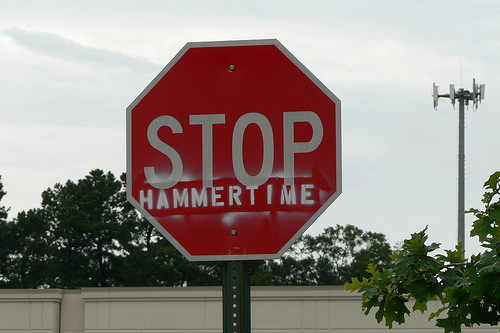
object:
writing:
[136, 179, 317, 210]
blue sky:
[332, 2, 482, 48]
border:
[186, 38, 276, 49]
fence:
[0, 287, 222, 330]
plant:
[347, 168, 500, 333]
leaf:
[344, 273, 368, 293]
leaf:
[412, 296, 431, 315]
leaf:
[437, 241, 467, 264]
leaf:
[424, 305, 447, 320]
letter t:
[190, 112, 227, 189]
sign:
[124, 37, 344, 267]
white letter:
[138, 190, 154, 210]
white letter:
[156, 185, 167, 208]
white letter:
[172, 186, 189, 208]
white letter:
[190, 189, 210, 207]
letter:
[191, 187, 209, 208]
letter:
[226, 185, 244, 206]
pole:
[218, 258, 251, 331]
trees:
[0, 168, 400, 286]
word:
[141, 111, 321, 193]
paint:
[134, 181, 320, 210]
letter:
[142, 114, 184, 190]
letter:
[231, 111, 275, 189]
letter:
[280, 109, 325, 186]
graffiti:
[138, 183, 317, 210]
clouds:
[1, 6, 499, 222]